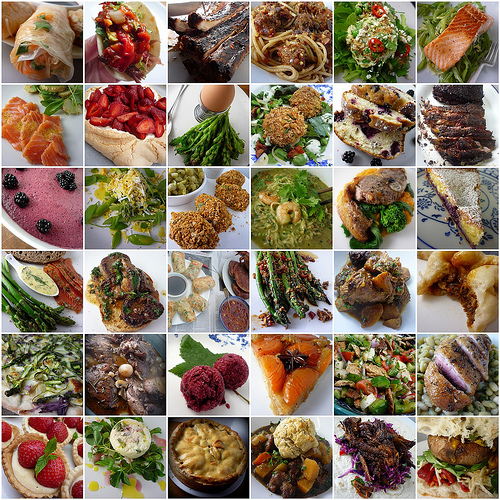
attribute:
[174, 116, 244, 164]
vegetable — green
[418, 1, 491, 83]
noodles — green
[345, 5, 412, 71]
slaw — green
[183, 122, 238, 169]
vegetable — green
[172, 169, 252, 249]
breaded objects — small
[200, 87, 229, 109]
egg — brown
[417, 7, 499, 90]
fish — cooked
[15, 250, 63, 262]
bread — brown, piece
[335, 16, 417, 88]
vegetable — green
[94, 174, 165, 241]
vegetable — green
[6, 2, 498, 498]
picture — small